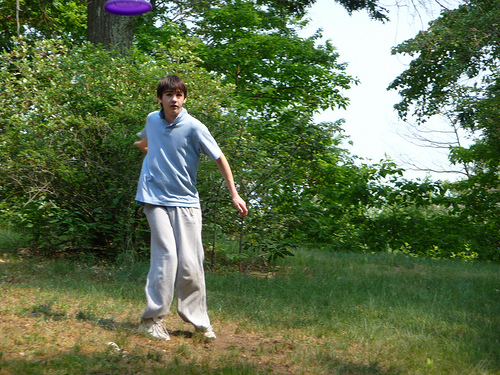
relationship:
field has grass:
[1, 244, 500, 374] [3, 245, 496, 373]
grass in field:
[3, 245, 496, 373] [1, 244, 500, 374]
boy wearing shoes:
[133, 76, 249, 343] [138, 318, 216, 344]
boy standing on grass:
[133, 76, 249, 343] [3, 245, 496, 373]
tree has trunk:
[0, 0, 391, 56] [85, 0, 135, 56]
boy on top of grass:
[133, 76, 249, 343] [3, 245, 496, 373]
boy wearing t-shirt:
[133, 76, 249, 343] [136, 107, 224, 210]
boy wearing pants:
[133, 76, 249, 343] [141, 206, 212, 329]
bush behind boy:
[1, 35, 297, 276] [133, 76, 249, 343]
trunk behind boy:
[85, 0, 135, 56] [133, 76, 249, 343]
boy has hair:
[133, 76, 249, 343] [157, 78, 189, 100]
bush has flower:
[1, 35, 297, 276] [59, 45, 67, 52]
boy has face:
[133, 76, 249, 343] [161, 88, 185, 114]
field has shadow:
[1, 244, 500, 374] [26, 303, 193, 339]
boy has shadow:
[133, 76, 249, 343] [26, 303, 193, 339]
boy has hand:
[133, 76, 249, 343] [232, 194, 248, 215]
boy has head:
[133, 76, 249, 343] [155, 77, 189, 115]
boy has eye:
[133, 76, 249, 343] [175, 93, 183, 100]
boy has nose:
[133, 76, 249, 343] [171, 96, 178, 104]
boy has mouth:
[133, 76, 249, 343] [171, 102, 179, 111]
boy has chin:
[133, 76, 249, 343] [170, 109, 181, 116]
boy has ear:
[133, 76, 249, 343] [157, 94, 164, 105]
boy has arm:
[133, 76, 249, 343] [192, 123, 238, 197]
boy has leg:
[133, 76, 249, 343] [144, 205, 178, 321]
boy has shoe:
[133, 76, 249, 343] [141, 319, 172, 340]